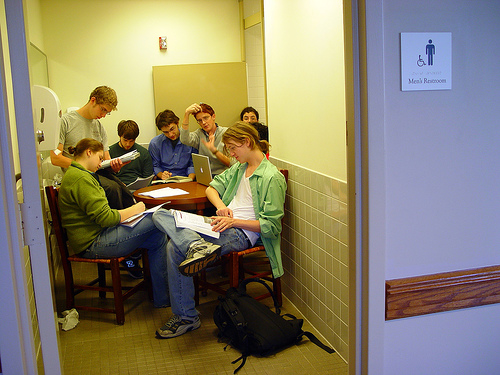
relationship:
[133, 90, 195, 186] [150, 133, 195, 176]
man wears shirt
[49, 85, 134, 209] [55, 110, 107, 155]
man wears t-shirt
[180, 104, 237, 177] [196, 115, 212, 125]
man wears glasses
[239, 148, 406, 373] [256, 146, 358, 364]
tiles on wall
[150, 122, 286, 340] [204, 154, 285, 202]
man wearing shirt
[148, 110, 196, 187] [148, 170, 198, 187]
man looking at paper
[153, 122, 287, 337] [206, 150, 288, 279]
man wears shirt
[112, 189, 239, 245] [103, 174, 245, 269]
book on lap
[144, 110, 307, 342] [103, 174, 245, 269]
man has lap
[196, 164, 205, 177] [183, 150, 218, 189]
apple sign on laptop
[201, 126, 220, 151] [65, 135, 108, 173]
hand on head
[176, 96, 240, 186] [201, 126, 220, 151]
woman has hand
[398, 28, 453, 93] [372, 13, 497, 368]
sign hanging on wall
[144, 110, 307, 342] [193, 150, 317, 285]
man wears shirt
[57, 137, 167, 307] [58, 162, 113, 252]
woman wears sweater